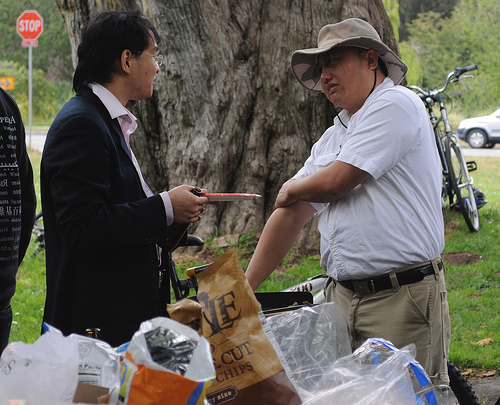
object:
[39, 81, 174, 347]
jacket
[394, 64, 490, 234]
bicycle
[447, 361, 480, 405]
tire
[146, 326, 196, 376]
inside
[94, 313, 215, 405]
bag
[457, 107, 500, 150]
car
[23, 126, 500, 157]
street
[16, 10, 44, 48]
sign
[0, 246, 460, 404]
sack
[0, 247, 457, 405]
table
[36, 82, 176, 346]
suit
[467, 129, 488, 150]
tire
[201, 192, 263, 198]
plate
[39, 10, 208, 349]
man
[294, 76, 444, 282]
shirt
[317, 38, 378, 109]
head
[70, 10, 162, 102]
head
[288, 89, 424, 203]
arm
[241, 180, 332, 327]
arm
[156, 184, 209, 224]
hand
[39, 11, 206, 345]
person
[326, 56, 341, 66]
eye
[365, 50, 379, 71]
ear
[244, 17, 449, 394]
person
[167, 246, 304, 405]
bag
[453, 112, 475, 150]
front end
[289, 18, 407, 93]
hat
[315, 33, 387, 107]
man's head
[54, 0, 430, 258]
trunk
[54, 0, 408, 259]
tree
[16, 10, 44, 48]
stop sign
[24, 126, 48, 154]
road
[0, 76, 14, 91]
street sign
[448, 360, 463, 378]
tread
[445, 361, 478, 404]
bike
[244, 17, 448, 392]
man